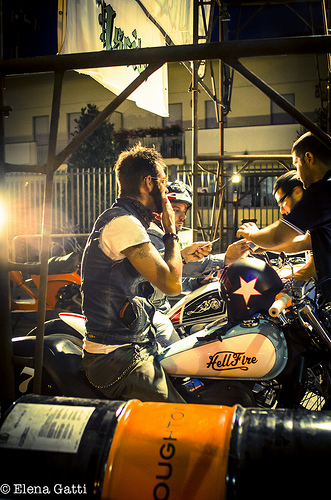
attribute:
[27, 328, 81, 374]
seat — black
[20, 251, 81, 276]
seat — black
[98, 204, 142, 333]
vest — blue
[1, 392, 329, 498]
barrel — black, orange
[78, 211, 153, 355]
shirt — white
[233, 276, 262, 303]
star — white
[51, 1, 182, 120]
flag — green, white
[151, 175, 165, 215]
beard — thick